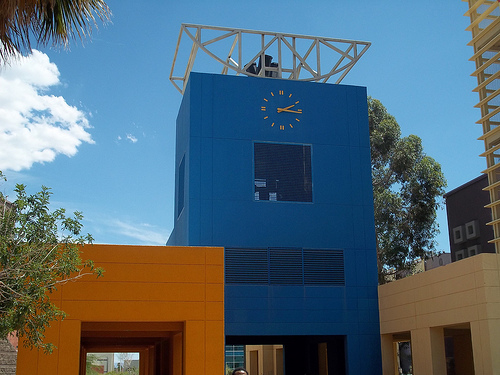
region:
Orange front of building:
[17, 240, 225, 372]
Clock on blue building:
[254, 85, 310, 135]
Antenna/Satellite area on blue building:
[166, 25, 378, 84]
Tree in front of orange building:
[1, 170, 84, 373]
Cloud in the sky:
[0, 26, 100, 183]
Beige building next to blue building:
[375, 251, 495, 373]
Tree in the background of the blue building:
[367, 92, 452, 284]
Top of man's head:
[226, 365, 256, 374]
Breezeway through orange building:
[72, 315, 204, 373]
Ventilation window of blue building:
[247, 140, 326, 207]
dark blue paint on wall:
[203, 141, 234, 168]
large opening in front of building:
[242, 138, 327, 213]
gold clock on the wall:
[243, 85, 315, 140]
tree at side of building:
[360, 98, 453, 254]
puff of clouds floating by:
[20, 103, 101, 142]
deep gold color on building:
[55, 260, 172, 303]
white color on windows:
[444, 218, 479, 243]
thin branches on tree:
[41, 270, 98, 283]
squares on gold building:
[133, 256, 214, 300]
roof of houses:
[400, 243, 449, 272]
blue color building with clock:
[173, 74, 393, 328]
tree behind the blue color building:
[374, 100, 444, 279]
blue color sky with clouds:
[11, 43, 135, 213]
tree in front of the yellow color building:
[13, 229, 215, 374]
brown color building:
[441, 175, 497, 262]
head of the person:
[228, 363, 253, 373]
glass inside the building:
[83, 348, 145, 373]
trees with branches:
[1, 190, 43, 337]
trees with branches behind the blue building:
[373, 94, 444, 284]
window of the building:
[226, 246, 352, 282]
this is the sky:
[96, 44, 125, 90]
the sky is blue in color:
[108, 33, 137, 68]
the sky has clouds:
[9, 56, 84, 174]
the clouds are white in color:
[18, 63, 57, 133]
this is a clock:
[256, 83, 313, 133]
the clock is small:
[255, 85, 310, 132]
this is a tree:
[372, 98, 440, 271]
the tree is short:
[375, 98, 452, 255]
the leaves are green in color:
[388, 235, 412, 251]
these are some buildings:
[120, 244, 464, 317]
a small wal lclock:
[256, 89, 308, 138]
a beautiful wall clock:
[234, 77, 332, 143]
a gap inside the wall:
[91, 337, 160, 372]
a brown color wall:
[13, 224, 243, 373]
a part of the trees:
[3, 200, 93, 368]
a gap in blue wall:
[216, 318, 389, 372]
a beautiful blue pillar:
[177, 47, 421, 357]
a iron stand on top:
[169, 22, 418, 94]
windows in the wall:
[403, 315, 492, 372]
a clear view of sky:
[26, 18, 497, 215]